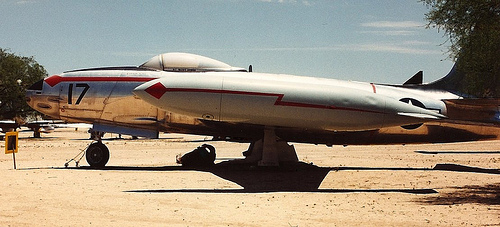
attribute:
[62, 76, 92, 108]
17 — number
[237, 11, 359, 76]
skies — clear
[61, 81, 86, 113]
seventeen — black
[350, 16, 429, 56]
cloud — white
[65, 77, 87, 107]
text — black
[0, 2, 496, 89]
sky — blue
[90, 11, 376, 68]
sky — blue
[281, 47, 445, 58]
snow — white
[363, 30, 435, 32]
snow — white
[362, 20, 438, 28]
snow — white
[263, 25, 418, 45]
sky — blue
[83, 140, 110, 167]
tire — black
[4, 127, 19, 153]
sign — yellow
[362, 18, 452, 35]
cloud — white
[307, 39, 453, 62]
cloud — white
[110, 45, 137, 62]
cloud — white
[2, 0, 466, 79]
sky — blue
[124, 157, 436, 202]
shadow — large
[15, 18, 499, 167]
plane — white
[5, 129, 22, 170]
sign — yellow, black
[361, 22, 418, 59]
clouds — white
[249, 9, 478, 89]
clouds — white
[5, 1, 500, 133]
sky — blue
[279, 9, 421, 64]
clouds — white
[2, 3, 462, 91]
sky — blue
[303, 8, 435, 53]
clouds — white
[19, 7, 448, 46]
sky — blue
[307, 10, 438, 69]
clouds — white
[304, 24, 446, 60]
clouds — white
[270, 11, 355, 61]
sky — blue